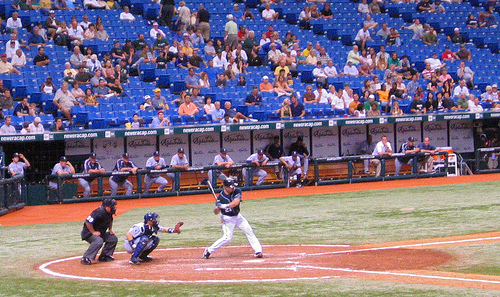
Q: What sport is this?
A: Baseball.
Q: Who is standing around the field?
A: Players in the dugout.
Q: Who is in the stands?
A: Spectators.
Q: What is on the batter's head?
A: Helmet.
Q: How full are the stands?
A: Less than half full.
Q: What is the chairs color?
A: Blue.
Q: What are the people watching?
A: Baseball.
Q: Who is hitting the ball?
A: Batter.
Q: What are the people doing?
A: Watching a game.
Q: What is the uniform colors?
A: White.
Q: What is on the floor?
A: Grass.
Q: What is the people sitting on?
A: Blue chair.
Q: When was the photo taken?
A: Daytime.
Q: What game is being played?
A: Baseball.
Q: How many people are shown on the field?
A: Three.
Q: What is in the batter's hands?
A: Bat.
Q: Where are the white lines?
A: Field.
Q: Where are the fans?
A: Stands.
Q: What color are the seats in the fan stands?
A: Blue.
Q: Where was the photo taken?
A: In a park.